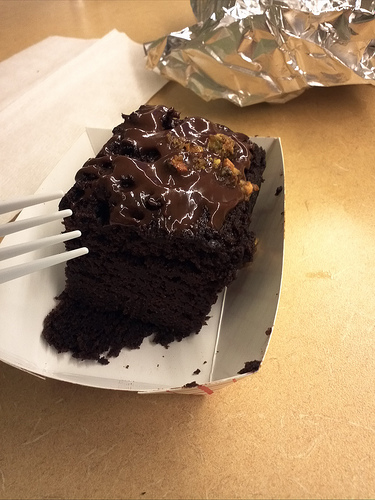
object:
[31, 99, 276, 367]
cake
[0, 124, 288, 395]
tray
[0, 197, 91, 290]
fork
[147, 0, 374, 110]
tinfoil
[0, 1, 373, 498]
counter top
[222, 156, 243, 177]
nut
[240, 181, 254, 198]
nut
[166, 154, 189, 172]
nut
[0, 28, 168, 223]
napkin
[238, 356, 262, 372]
piece of cake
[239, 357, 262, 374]
corner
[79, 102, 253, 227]
chocolate icing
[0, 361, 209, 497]
shadow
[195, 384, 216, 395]
stripe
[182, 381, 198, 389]
brownie crumbs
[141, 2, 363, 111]
paper